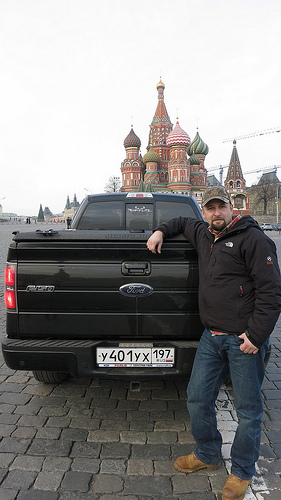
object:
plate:
[97, 347, 174, 367]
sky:
[0, 0, 279, 217]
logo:
[119, 283, 154, 298]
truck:
[1, 193, 270, 385]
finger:
[238, 333, 244, 338]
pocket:
[237, 333, 258, 355]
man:
[144, 183, 278, 498]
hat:
[198, 182, 233, 206]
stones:
[205, 407, 270, 485]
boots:
[171, 448, 249, 496]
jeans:
[185, 328, 266, 482]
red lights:
[4, 266, 15, 310]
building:
[120, 78, 251, 216]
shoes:
[222, 470, 252, 499]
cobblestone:
[56, 469, 220, 491]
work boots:
[170, 453, 256, 499]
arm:
[162, 216, 204, 236]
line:
[213, 383, 272, 498]